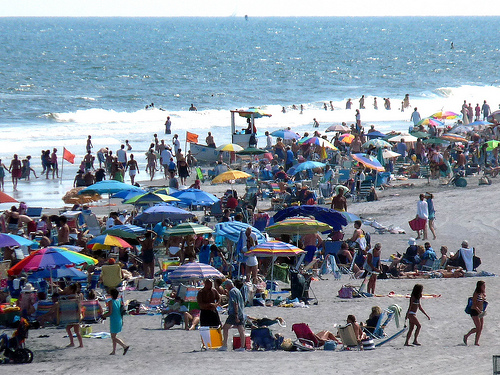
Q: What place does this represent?
A: It represents the beach.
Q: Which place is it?
A: It is a beach.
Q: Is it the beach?
A: Yes, it is the beach.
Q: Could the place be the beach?
A: Yes, it is the beach.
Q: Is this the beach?
A: Yes, it is the beach.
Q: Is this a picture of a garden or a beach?
A: It is showing a beach.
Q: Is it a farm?
A: No, it is a beach.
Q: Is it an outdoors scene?
A: Yes, it is outdoors.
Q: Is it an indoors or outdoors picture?
A: It is outdoors.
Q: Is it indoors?
A: No, it is outdoors.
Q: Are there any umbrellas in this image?
A: Yes, there is an umbrella.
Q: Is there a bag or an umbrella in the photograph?
A: Yes, there is an umbrella.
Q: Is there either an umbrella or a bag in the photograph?
A: Yes, there is an umbrella.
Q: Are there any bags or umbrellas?
A: Yes, there is an umbrella.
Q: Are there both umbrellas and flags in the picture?
A: Yes, there are both an umbrella and a flag.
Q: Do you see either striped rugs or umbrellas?
A: Yes, there is a striped umbrella.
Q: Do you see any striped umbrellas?
A: Yes, there is a striped umbrella.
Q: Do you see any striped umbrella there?
A: Yes, there is a striped umbrella.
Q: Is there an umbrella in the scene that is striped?
A: Yes, there is an umbrella that is striped.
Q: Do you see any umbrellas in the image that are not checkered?
A: Yes, there is a striped umbrella.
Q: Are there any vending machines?
A: No, there are no vending machines.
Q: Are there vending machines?
A: No, there are no vending machines.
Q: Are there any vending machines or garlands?
A: No, there are no vending machines or garlands.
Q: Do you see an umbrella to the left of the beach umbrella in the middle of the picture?
A: Yes, there is an umbrella to the left of the beach umbrella.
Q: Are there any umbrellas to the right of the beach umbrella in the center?
A: No, the umbrella is to the left of the beach umbrella.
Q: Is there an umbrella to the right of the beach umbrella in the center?
A: No, the umbrella is to the left of the beach umbrella.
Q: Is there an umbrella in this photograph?
A: Yes, there is an umbrella.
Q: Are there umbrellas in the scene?
A: Yes, there is an umbrella.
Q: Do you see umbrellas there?
A: Yes, there is an umbrella.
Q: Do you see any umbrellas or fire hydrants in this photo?
A: Yes, there is an umbrella.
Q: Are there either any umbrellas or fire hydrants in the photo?
A: Yes, there is an umbrella.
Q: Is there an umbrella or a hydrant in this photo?
A: Yes, there is an umbrella.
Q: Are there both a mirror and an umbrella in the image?
A: No, there is an umbrella but no mirrors.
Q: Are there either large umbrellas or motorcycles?
A: Yes, there is a large umbrella.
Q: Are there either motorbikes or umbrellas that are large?
A: Yes, the umbrella is large.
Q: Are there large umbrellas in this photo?
A: Yes, there is a large umbrella.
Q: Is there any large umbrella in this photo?
A: Yes, there is a large umbrella.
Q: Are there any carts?
A: No, there are no carts.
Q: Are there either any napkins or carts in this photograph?
A: No, there are no carts or napkins.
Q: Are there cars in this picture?
A: No, there are no cars.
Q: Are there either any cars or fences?
A: No, there are no cars or fences.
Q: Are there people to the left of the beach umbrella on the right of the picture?
A: Yes, there are people to the left of the beach umbrella.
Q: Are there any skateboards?
A: No, there are no skateboards.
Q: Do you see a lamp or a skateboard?
A: No, there are no skateboards or lamps.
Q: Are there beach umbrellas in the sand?
A: Yes, there is a beach umbrella in the sand.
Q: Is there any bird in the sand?
A: No, there is a beach umbrella in the sand.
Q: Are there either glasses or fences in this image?
A: No, there are no fences or glasses.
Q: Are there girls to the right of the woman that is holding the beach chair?
A: Yes, there is a girl to the right of the woman.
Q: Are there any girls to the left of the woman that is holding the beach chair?
A: No, the girl is to the right of the woman.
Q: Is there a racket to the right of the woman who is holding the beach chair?
A: No, there is a girl to the right of the woman.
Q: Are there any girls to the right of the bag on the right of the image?
A: Yes, there is a girl to the right of the bag.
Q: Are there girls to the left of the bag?
A: No, the girl is to the right of the bag.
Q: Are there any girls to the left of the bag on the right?
A: No, the girl is to the right of the bag.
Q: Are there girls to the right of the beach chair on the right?
A: Yes, there is a girl to the right of the beach chair.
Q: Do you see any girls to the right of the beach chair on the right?
A: Yes, there is a girl to the right of the beach chair.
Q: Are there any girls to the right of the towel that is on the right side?
A: Yes, there is a girl to the right of the towel.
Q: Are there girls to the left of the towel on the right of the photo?
A: No, the girl is to the right of the towel.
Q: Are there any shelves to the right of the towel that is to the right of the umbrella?
A: No, there is a girl to the right of the towel.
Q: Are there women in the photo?
A: Yes, there is a woman.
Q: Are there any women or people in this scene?
A: Yes, there is a woman.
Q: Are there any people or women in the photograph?
A: Yes, there is a woman.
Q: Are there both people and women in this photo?
A: Yes, there are both a woman and people.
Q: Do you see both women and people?
A: Yes, there are both a woman and people.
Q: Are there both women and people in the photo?
A: Yes, there are both a woman and people.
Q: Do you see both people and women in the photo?
A: Yes, there are both a woman and people.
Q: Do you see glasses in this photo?
A: No, there are no glasses.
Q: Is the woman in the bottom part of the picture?
A: Yes, the woman is in the bottom of the image.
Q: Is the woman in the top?
A: No, the woman is in the bottom of the image.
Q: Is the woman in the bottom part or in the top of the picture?
A: The woman is in the bottom of the image.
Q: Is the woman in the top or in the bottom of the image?
A: The woman is in the bottom of the image.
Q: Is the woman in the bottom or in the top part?
A: The woman is in the bottom of the image.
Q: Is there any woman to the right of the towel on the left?
A: Yes, there is a woman to the right of the towel.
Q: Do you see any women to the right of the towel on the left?
A: Yes, there is a woman to the right of the towel.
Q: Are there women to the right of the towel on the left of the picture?
A: Yes, there is a woman to the right of the towel.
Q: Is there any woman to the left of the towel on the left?
A: No, the woman is to the right of the towel.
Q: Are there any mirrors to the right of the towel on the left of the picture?
A: No, there is a woman to the right of the towel.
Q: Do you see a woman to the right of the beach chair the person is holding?
A: Yes, there is a woman to the right of the beach chair.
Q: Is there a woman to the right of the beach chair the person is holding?
A: Yes, there is a woman to the right of the beach chair.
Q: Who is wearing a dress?
A: The woman is wearing a dress.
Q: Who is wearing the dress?
A: The woman is wearing a dress.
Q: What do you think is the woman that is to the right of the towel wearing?
A: The woman is wearing a dress.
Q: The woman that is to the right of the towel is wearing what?
A: The woman is wearing a dress.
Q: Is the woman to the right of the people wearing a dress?
A: Yes, the woman is wearing a dress.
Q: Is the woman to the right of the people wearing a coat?
A: No, the woman is wearing a dress.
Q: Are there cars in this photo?
A: No, there are no cars.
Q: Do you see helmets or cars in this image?
A: No, there are no cars or helmets.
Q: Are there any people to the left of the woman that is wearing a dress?
A: Yes, there is a person to the left of the woman.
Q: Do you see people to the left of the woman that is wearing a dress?
A: Yes, there is a person to the left of the woman.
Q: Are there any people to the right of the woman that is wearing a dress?
A: No, the person is to the left of the woman.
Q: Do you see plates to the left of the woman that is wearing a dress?
A: No, there is a person to the left of the woman.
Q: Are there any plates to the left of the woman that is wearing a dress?
A: No, there is a person to the left of the woman.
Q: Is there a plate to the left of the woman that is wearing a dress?
A: No, there is a person to the left of the woman.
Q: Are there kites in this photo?
A: No, there are no kites.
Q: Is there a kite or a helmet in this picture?
A: No, there are no kites or helmets.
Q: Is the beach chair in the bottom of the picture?
A: Yes, the beach chair is in the bottom of the image.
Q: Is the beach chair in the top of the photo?
A: No, the beach chair is in the bottom of the image.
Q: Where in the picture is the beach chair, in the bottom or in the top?
A: The beach chair is in the bottom of the image.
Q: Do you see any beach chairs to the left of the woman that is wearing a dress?
A: Yes, there is a beach chair to the left of the woman.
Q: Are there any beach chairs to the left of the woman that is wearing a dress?
A: Yes, there is a beach chair to the left of the woman.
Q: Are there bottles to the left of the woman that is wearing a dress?
A: No, there is a beach chair to the left of the woman.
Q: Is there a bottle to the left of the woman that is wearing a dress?
A: No, there is a beach chair to the left of the woman.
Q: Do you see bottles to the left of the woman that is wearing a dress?
A: No, there is a beach chair to the left of the woman.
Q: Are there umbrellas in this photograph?
A: Yes, there is an umbrella.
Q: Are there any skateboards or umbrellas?
A: Yes, there is an umbrella.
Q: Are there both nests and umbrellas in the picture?
A: No, there is an umbrella but no nests.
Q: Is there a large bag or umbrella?
A: Yes, there is a large umbrella.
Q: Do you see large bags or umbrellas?
A: Yes, there is a large umbrella.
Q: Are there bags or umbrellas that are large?
A: Yes, the umbrella is large.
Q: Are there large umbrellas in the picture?
A: Yes, there is a large umbrella.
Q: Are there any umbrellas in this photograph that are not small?
A: Yes, there is a large umbrella.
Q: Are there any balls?
A: No, there are no balls.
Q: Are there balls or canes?
A: No, there are no balls or canes.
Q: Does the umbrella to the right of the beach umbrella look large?
A: Yes, the umbrella is large.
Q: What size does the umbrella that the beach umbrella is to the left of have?
A: The umbrella has large size.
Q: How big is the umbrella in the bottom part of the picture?
A: The umbrella is large.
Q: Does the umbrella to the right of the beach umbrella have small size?
A: No, the umbrella is large.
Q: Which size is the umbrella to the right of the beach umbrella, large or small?
A: The umbrella is large.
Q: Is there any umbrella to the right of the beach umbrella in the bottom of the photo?
A: Yes, there is an umbrella to the right of the beach umbrella.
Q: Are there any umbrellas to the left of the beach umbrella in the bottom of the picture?
A: No, the umbrella is to the right of the beach umbrella.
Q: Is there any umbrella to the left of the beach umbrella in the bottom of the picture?
A: No, the umbrella is to the right of the beach umbrella.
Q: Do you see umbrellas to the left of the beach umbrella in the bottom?
A: No, the umbrella is to the right of the beach umbrella.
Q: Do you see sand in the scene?
A: Yes, there is sand.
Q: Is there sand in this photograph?
A: Yes, there is sand.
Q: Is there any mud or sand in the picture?
A: Yes, there is sand.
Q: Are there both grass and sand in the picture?
A: No, there is sand but no grass.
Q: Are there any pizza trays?
A: No, there are no pizza trays.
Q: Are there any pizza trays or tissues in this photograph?
A: No, there are no pizza trays or tissues.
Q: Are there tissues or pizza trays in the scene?
A: No, there are no pizza trays or tissues.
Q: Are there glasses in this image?
A: No, there are no glasses.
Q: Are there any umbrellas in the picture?
A: Yes, there is an umbrella.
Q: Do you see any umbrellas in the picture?
A: Yes, there is an umbrella.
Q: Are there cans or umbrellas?
A: Yes, there is an umbrella.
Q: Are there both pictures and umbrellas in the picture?
A: No, there is an umbrella but no pictures.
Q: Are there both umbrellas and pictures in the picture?
A: No, there is an umbrella but no pictures.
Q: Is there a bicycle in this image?
A: No, there are no bicycles.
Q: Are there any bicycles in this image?
A: No, there are no bicycles.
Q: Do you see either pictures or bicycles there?
A: No, there are no bicycles or pictures.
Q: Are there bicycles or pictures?
A: No, there are no bicycles or pictures.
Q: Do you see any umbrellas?
A: Yes, there is an umbrella.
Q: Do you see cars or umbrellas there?
A: Yes, there is an umbrella.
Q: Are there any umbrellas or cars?
A: Yes, there is an umbrella.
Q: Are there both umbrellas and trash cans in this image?
A: No, there is an umbrella but no trash cans.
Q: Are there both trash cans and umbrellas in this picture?
A: No, there is an umbrella but no trash cans.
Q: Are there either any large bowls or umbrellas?
A: Yes, there is a large umbrella.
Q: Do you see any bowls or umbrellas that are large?
A: Yes, the umbrella is large.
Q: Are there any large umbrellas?
A: Yes, there is a large umbrella.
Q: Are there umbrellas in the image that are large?
A: Yes, there is an umbrella that is large.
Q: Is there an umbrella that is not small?
A: Yes, there is a large umbrella.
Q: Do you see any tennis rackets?
A: No, there are no tennis rackets.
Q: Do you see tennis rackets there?
A: No, there are no tennis rackets.